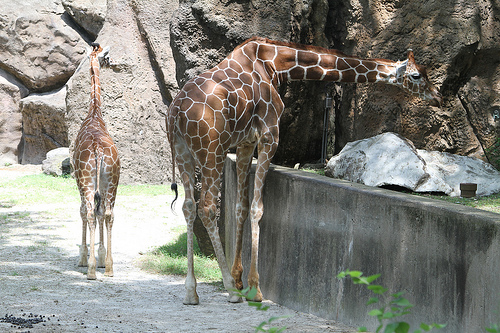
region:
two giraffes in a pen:
[54, 22, 445, 314]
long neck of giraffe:
[262, 33, 449, 107]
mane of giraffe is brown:
[242, 33, 404, 65]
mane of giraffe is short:
[239, 34, 399, 66]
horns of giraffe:
[401, 39, 418, 66]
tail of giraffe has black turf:
[87, 139, 109, 222]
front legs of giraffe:
[233, 140, 277, 305]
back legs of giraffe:
[174, 156, 245, 311]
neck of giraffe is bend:
[162, 25, 442, 311]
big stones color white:
[320, 125, 498, 201]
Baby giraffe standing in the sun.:
[74, 47, 129, 278]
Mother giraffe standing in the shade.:
[153, 45, 444, 309]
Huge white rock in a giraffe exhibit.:
[327, 131, 497, 195]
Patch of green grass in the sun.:
[158, 234, 228, 282]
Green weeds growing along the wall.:
[344, 267, 459, 332]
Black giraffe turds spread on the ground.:
[5, 290, 86, 331]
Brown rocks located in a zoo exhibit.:
[185, 2, 477, 31]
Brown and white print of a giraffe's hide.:
[193, 87, 268, 122]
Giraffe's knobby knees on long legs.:
[184, 194, 265, 230]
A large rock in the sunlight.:
[40, 145, 76, 181]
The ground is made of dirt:
[21, 279, 177, 325]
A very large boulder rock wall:
[15, 0, 65, 160]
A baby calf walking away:
[71, 38, 126, 282]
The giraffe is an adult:
[161, 31, 446, 306]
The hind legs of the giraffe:
[176, 158, 238, 311]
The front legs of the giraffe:
[233, 141, 274, 299]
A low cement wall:
[301, 161, 499, 331]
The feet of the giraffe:
[181, 285, 268, 309]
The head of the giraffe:
[398, 48, 446, 109]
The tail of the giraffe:
[166, 93, 186, 215]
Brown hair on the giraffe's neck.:
[271, 20, 356, 67]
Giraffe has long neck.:
[269, 25, 399, 96]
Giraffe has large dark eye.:
[410, 58, 440, 106]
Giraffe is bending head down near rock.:
[329, 33, 449, 122]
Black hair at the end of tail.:
[165, 183, 200, 205]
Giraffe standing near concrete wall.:
[163, 163, 333, 303]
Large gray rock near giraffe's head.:
[331, 127, 466, 201]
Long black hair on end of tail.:
[88, 176, 104, 217]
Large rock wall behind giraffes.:
[21, 21, 177, 149]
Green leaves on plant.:
[344, 254, 385, 305]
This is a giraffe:
[61, 34, 142, 302]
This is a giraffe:
[150, 31, 458, 311]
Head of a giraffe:
[391, 42, 464, 128]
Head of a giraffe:
[82, 37, 120, 73]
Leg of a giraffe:
[247, 119, 282, 311]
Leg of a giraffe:
[231, 130, 253, 302]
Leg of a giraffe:
[198, 143, 239, 308]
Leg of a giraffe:
[172, 139, 203, 308]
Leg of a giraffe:
[105, 173, 127, 281]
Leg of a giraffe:
[87, 170, 95, 282]